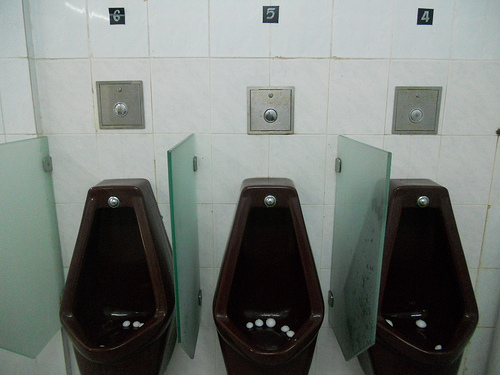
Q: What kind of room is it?
A: It is a bathroom.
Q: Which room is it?
A: It is a bathroom.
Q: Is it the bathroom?
A: Yes, it is the bathroom.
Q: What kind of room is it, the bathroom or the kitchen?
A: It is the bathroom.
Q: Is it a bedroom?
A: No, it is a bathroom.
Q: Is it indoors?
A: Yes, it is indoors.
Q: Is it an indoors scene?
A: Yes, it is indoors.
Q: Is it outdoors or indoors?
A: It is indoors.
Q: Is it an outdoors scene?
A: No, it is indoors.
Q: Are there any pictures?
A: No, there are no pictures.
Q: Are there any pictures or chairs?
A: No, there are no pictures or chairs.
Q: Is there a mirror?
A: Yes, there is a mirror.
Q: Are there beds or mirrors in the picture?
A: Yes, there is a mirror.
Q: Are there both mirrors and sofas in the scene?
A: No, there is a mirror but no sofas.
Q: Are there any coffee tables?
A: No, there are no coffee tables.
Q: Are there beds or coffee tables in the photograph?
A: No, there are no coffee tables or beds.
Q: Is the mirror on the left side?
A: Yes, the mirror is on the left of the image.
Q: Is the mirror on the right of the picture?
A: No, the mirror is on the left of the image.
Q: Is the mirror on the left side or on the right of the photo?
A: The mirror is on the left of the image.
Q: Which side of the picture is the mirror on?
A: The mirror is on the left of the image.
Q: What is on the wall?
A: The mirror is on the wall.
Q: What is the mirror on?
A: The mirror is on the wall.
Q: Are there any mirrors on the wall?
A: Yes, there is a mirror on the wall.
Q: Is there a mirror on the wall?
A: Yes, there is a mirror on the wall.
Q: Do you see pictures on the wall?
A: No, there is a mirror on the wall.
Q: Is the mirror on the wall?
A: Yes, the mirror is on the wall.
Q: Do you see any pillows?
A: No, there are no pillows.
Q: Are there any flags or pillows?
A: No, there are no pillows or flags.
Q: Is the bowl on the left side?
A: Yes, the bowl is on the left of the image.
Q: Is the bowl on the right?
A: No, the bowl is on the left of the image.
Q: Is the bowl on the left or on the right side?
A: The bowl is on the left of the image.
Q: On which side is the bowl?
A: The bowl is on the left of the image.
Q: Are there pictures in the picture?
A: No, there are no pictures.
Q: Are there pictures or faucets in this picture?
A: No, there are no pictures or faucets.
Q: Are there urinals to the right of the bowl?
A: Yes, there is a urinal to the right of the bowl.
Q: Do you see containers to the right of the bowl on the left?
A: No, there is a urinal to the right of the bowl.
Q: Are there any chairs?
A: No, there are no chairs.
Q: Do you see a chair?
A: No, there are no chairs.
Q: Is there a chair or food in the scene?
A: No, there are no chairs or food.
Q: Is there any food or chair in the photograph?
A: No, there are no chairs or food.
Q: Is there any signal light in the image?
A: No, there are no traffic lights.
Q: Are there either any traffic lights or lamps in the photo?
A: No, there are no traffic lights or lamps.